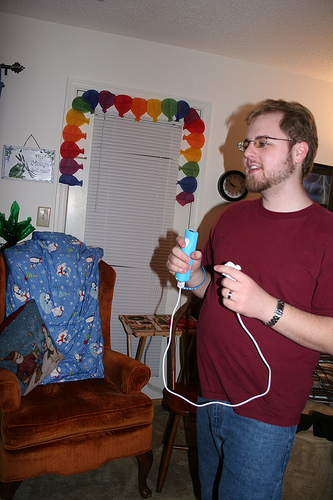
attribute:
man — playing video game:
[166, 98, 332, 499]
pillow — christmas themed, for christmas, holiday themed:
[2, 298, 64, 397]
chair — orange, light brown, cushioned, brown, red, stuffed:
[1, 258, 154, 500]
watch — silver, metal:
[264, 298, 285, 328]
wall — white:
[1, 13, 332, 388]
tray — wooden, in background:
[118, 312, 198, 338]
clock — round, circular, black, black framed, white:
[217, 169, 249, 203]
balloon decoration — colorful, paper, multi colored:
[60, 89, 206, 208]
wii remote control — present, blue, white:
[161, 230, 272, 409]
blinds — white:
[85, 111, 180, 376]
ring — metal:
[226, 289, 236, 302]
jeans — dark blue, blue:
[194, 395, 298, 499]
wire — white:
[161, 284, 271, 410]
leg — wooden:
[135, 449, 156, 500]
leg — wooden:
[1, 479, 26, 499]